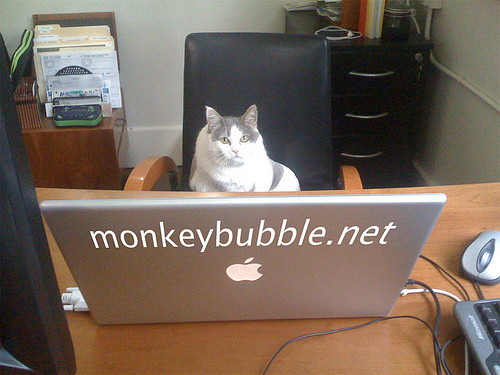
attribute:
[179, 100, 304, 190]
cat — white, sitting, fat, gray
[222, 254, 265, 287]
logo — apple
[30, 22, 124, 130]
envelopes — stacked, yellow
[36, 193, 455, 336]
laptop — open , back , macbook, silver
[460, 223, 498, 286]
mouse — gray, black, wired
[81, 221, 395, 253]
text — website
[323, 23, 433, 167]
drawer — black, file ,  back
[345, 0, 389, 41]
group —  books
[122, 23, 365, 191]
chair — black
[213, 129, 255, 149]
eyes — green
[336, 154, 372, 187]
handles — brown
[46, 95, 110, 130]
device — green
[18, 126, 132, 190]
cabinet — wooden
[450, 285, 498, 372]
keyboard — black